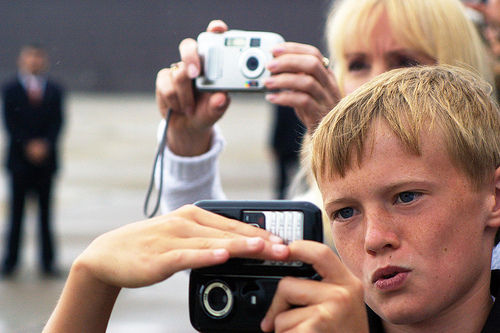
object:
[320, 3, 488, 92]
hair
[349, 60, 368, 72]
eye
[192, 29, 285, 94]
camera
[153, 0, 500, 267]
woman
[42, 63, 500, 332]
boy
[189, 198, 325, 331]
cell phone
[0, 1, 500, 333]
picture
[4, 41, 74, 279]
man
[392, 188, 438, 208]
eyes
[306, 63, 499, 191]
hair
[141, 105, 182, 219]
strap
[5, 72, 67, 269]
suit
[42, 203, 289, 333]
hands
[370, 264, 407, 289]
mouth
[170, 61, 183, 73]
ring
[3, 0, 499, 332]
background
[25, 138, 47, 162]
hands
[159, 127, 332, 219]
shirt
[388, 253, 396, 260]
mole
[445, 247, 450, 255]
mole